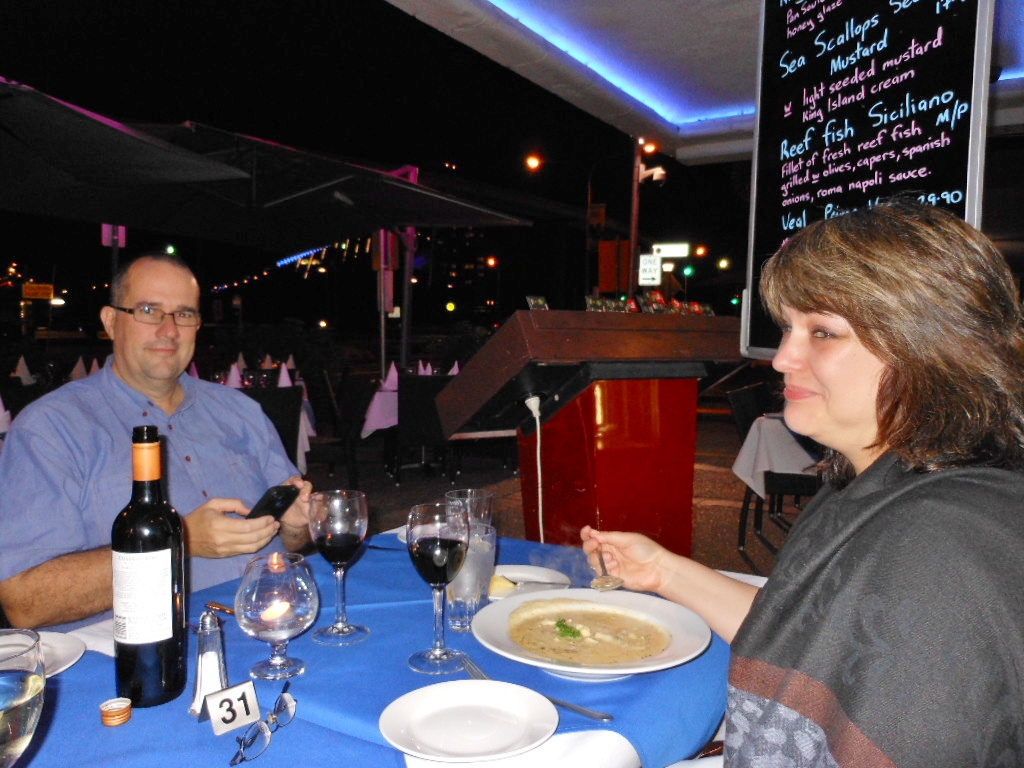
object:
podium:
[433, 312, 737, 546]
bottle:
[106, 423, 197, 707]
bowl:
[466, 581, 712, 679]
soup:
[507, 603, 680, 670]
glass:
[406, 502, 471, 680]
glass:
[306, 487, 374, 642]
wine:
[306, 534, 374, 572]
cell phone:
[243, 483, 301, 522]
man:
[0, 250, 324, 610]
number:
[217, 692, 254, 728]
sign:
[206, 683, 264, 735]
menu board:
[734, 0, 1000, 365]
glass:
[232, 546, 323, 680]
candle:
[232, 591, 315, 637]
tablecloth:
[0, 538, 720, 768]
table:
[0, 536, 751, 763]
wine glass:
[400, 500, 483, 678]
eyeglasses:
[98, 298, 213, 330]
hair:
[770, 206, 1009, 464]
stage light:
[524, 157, 541, 170]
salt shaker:
[180, 607, 234, 718]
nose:
[767, 329, 810, 372]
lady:
[689, 207, 1021, 768]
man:
[0, 259, 297, 612]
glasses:
[442, 490, 482, 632]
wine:
[401, 536, 473, 586]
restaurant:
[13, 19, 1012, 748]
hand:
[183, 498, 287, 562]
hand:
[279, 471, 323, 533]